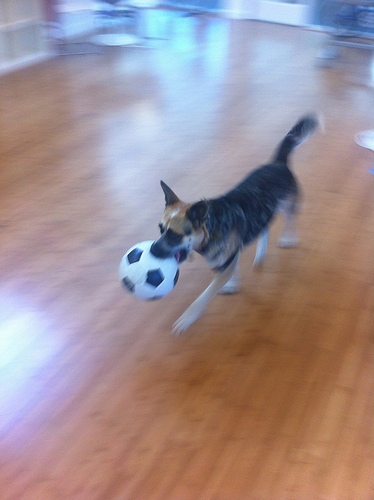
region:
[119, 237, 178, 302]
black and white soccer ball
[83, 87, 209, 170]
shiny wood floor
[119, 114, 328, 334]
dog holding ball in its mouth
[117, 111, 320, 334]
the dog is running across the floor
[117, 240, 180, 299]
the ball is in the dog's mouth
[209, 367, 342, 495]
the floor is brown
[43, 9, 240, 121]
the background is blurry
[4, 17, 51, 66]
the wall has wainscoting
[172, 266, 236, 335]
the dog's legs are white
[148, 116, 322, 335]
the dog is brown, black and white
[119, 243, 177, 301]
The soccer ball in the dog's mouth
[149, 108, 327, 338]
The dog carrying the ball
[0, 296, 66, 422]
Light reflecting off the floor in front of the dog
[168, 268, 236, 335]
Dog's leg that is not on the ground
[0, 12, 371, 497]
The hardwood floor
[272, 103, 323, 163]
The dog's tail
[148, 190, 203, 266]
The head of the dog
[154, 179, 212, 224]
The ears of the dog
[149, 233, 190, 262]
The snout of the dog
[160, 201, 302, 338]
The legs of the dog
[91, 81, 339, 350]
dog running with a ball.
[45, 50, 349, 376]
excited dog running with a ball.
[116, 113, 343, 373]
hyper dog running with a ball.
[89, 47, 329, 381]
dog playing with a soccer ball.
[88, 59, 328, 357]
excited dog playing with a soccer ball.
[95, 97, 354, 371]
happy dog playing with a soccer ball.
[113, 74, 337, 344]
dog playing with soccer ball on wooden floor.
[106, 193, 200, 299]
soccer ball in dog's mouth.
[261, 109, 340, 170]
wagging tail of a dog.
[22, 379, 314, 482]
patch of a wooden floor.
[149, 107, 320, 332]
tan, white and black mixed breed young dog playing with ball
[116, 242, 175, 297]
white soccer ball with black pentagons being carried by dog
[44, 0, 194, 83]
blurred furniture at the back of the large room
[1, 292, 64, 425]
glare where sun reflects on polished wooden floor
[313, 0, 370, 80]
blurred furniture at back of the large room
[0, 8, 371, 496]
highly polished wood laminate flooring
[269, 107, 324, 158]
bushy black and white tail held high by dog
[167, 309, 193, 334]
dogs front left paw is the only paw off the floor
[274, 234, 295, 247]
dogs left rear paw is solidly on the wooden floor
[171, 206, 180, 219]
small white spot between the dogs ears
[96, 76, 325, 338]
dog walking across wooden floor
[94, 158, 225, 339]
dog holding soccer ball in mouth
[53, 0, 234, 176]
room with a bare floor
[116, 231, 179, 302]
black pentagons on a white ball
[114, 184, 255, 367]
dog walking with left leg in front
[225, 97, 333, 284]
tail up on dog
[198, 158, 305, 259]
black body with grey hairs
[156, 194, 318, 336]
light-colored legs under darker body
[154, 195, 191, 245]
thin white mark on top of head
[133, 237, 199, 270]
mouth open wide around ball